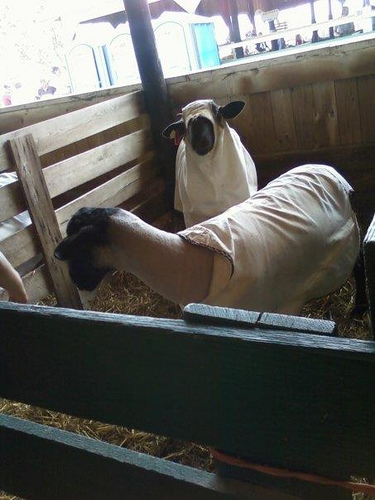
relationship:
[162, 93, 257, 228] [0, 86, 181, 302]
sheep in fence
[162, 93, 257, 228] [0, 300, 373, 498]
sheep in fence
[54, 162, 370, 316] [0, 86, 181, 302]
body in fence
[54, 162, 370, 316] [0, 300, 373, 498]
body in fence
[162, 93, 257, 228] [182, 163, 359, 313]
sheep wearing covering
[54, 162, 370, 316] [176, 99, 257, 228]
body wearing covering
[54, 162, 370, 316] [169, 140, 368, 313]
body wearing covering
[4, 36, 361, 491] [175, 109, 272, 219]
fences with sheep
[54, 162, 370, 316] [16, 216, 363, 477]
body standing in hay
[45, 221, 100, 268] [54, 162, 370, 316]
ear of body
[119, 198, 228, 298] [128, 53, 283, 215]
neck of sheep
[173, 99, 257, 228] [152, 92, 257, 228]
covering over sheep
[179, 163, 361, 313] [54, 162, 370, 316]
covering covering body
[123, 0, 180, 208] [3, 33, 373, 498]
pole in pen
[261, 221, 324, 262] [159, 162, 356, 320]
cloth covering body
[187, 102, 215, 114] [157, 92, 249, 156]
cloth covering head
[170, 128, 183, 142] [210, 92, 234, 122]
tag on ear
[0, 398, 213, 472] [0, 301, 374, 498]
straw through planks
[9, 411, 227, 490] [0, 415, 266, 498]
light reflecting on plank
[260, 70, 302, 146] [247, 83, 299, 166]
plank joining plank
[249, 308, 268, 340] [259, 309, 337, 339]
joint on vertical plank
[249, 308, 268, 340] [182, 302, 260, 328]
joint on vertical plank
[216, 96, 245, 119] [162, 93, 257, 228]
ear of sheep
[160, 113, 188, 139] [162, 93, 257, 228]
ear of sheep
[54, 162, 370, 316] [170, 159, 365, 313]
body wearing cloth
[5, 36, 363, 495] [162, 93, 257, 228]
area with sheep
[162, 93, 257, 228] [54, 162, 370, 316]
sheep with body